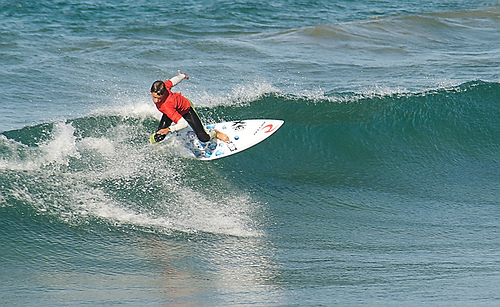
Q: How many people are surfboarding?
A: One.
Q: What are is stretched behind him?
A: His right.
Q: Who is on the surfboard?
A: The boy.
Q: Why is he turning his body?
A: To ride the wave.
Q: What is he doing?
A: Surfboarding.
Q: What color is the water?
A: Blue.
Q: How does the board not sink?
A: It floats.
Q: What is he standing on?
A: The surfboard.